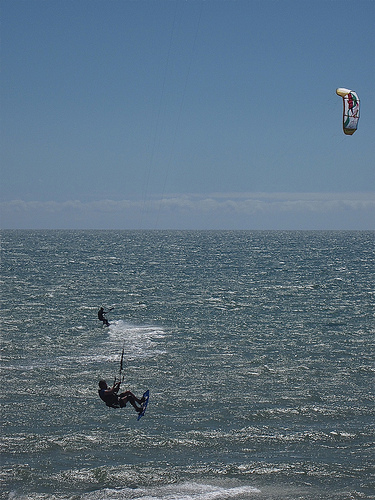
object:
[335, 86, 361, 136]
kite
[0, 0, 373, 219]
sky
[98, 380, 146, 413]
man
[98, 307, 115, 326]
man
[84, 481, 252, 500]
wave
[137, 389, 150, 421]
board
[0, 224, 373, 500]
water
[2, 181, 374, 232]
clouds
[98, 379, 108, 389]
head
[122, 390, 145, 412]
legs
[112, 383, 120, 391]
hands